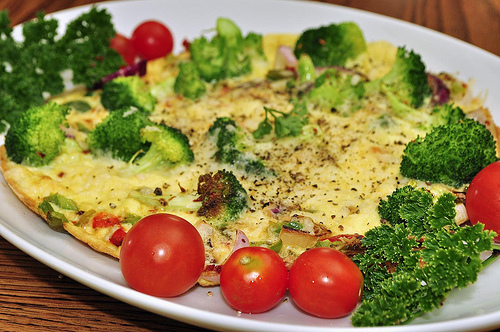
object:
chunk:
[91, 207, 125, 247]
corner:
[327, 0, 499, 62]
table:
[0, 252, 185, 328]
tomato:
[287, 246, 365, 318]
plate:
[0, 0, 500, 332]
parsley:
[0, 7, 125, 119]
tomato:
[96, 30, 135, 73]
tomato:
[220, 246, 290, 314]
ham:
[428, 72, 447, 107]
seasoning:
[283, 138, 341, 188]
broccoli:
[139, 123, 194, 165]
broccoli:
[101, 73, 160, 112]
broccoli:
[291, 20, 366, 70]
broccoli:
[361, 44, 426, 109]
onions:
[275, 42, 300, 77]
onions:
[195, 217, 249, 277]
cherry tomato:
[121, 213, 203, 296]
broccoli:
[86, 105, 156, 165]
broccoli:
[199, 167, 246, 227]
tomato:
[463, 157, 497, 244]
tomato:
[132, 18, 173, 62]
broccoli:
[395, 102, 496, 184]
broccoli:
[2, 100, 70, 165]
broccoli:
[340, 183, 496, 324]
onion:
[273, 224, 317, 253]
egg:
[0, 33, 497, 288]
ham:
[274, 43, 299, 72]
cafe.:
[0, 0, 499, 330]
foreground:
[1, 212, 498, 330]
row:
[118, 213, 365, 319]